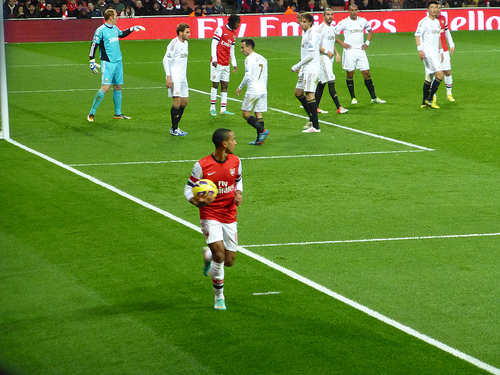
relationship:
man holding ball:
[182, 129, 244, 312] [193, 179, 220, 204]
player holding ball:
[182, 129, 244, 312] [193, 179, 220, 204]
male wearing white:
[338, 2, 386, 102] [335, 18, 371, 70]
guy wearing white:
[209, 15, 237, 116] [211, 59, 234, 81]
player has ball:
[182, 129, 244, 312] [193, 179, 220, 204]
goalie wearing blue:
[86, 10, 145, 124] [88, 24, 123, 119]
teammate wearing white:
[417, 0, 440, 110] [335, 18, 371, 70]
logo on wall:
[199, 16, 398, 40] [106, 9, 499, 39]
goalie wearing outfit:
[86, 10, 145, 124] [86, 24, 132, 119]